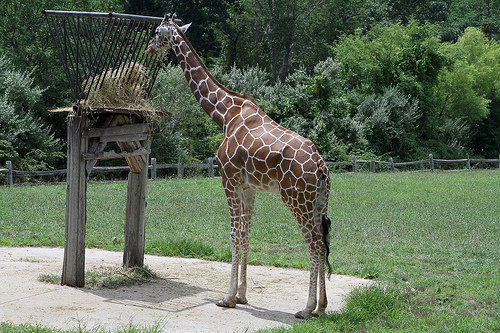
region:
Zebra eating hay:
[141, 13, 191, 69]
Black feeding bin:
[34, 7, 176, 110]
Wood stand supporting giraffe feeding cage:
[58, 116, 153, 287]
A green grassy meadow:
[343, 170, 493, 283]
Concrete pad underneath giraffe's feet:
[60, 253, 365, 330]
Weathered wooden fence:
[347, 151, 494, 171]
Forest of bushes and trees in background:
[290, 5, 498, 131]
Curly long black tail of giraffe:
[320, 207, 335, 282]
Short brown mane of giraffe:
[173, 28, 253, 109]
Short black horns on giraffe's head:
[159, 12, 184, 23]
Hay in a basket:
[35, 2, 177, 118]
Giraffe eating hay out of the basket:
[148, 14, 373, 321]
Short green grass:
[372, 182, 452, 283]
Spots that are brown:
[235, 115, 292, 164]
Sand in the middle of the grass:
[128, 277, 188, 331]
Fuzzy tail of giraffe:
[314, 155, 346, 277]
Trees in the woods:
[313, 10, 443, 153]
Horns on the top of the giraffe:
[160, 9, 181, 26]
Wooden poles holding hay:
[56, 111, 185, 294]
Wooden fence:
[2, 152, 64, 201]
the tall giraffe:
[152, 15, 328, 314]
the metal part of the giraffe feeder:
[46, 5, 163, 99]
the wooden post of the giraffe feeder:
[67, 110, 147, 285]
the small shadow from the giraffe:
[235, 298, 301, 329]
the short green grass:
[341, 174, 497, 272]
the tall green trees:
[325, 4, 498, 151]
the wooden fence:
[345, 156, 497, 171]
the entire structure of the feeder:
[39, 7, 177, 288]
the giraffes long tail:
[320, 162, 333, 283]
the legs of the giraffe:
[223, 175, 327, 321]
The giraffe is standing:
[141, 12, 348, 312]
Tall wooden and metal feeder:
[42, 3, 182, 293]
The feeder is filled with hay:
[46, 5, 187, 126]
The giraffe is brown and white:
[139, 9, 333, 329]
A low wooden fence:
[10, 144, 485, 193]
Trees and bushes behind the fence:
[21, 27, 482, 168]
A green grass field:
[148, 103, 486, 273]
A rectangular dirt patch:
[8, 229, 368, 320]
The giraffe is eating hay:
[135, 8, 350, 323]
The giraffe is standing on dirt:
[143, 10, 362, 325]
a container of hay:
[75, 47, 163, 129]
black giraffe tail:
[314, 190, 341, 281]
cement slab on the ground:
[2, 236, 376, 331]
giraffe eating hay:
[146, 7, 348, 315]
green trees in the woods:
[325, 17, 498, 162]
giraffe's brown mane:
[174, 25, 253, 110]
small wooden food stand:
[58, 97, 161, 282]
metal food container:
[38, 6, 168, 121]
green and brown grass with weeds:
[373, 200, 484, 313]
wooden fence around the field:
[352, 151, 498, 181]